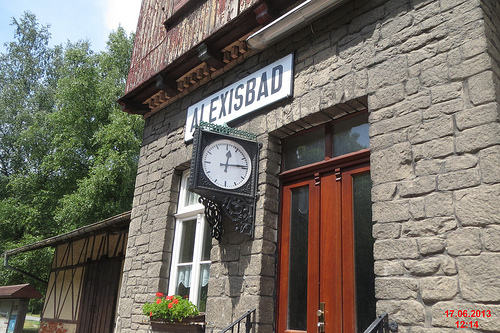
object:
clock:
[201, 139, 252, 192]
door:
[274, 108, 377, 332]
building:
[114, 0, 499, 332]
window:
[161, 162, 208, 318]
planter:
[146, 313, 205, 333]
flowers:
[150, 294, 167, 304]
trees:
[0, 8, 55, 170]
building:
[3, 209, 133, 332]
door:
[74, 255, 124, 332]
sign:
[184, 50, 293, 142]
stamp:
[445, 308, 493, 328]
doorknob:
[317, 300, 325, 331]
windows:
[287, 183, 312, 332]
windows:
[279, 119, 330, 175]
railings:
[217, 308, 260, 332]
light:
[247, 0, 341, 50]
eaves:
[114, 0, 299, 118]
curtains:
[177, 265, 209, 287]